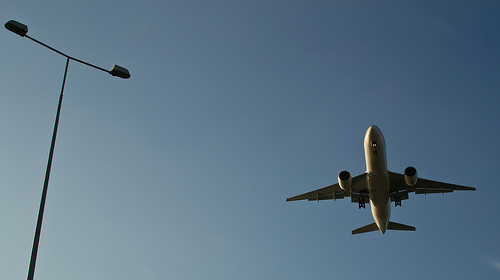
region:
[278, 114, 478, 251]
a plane taking off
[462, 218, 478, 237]
a red balloon flying in the air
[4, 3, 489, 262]
a blue sky with plane flying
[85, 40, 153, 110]
a part of a light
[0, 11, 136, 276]
a light fixture hanging from a pole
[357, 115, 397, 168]
a front of the plane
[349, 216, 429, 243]
the tail of the plane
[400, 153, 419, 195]
a right engine of the plane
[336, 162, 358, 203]
a left engine of the plane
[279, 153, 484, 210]
wings of a airplane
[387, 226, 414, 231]
elevator flight control surface on an airplane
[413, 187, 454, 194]
landing flaps on an airplane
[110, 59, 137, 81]
light fixture on outdoor lighting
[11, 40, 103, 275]
support structure for outdoor lights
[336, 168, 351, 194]
jet engine on passenger jet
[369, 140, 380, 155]
landing gear or on passenger jet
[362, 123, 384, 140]
flightdeck on a passenger jet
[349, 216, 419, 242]
horizontal stabilizers on an airplane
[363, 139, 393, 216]
main fuselage of passenger jet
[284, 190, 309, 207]
wing tip on a commercial airliner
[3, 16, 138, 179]
Lights on a pole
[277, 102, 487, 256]
Airplane in the sky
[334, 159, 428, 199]
Twin engines on a plane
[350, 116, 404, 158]
Silver nose of an airplane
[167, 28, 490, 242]
A cloudless sky where a plane flies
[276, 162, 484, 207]
Wings and engines of an airplane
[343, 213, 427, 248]
The tail of a plane in flight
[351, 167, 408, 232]
Landing gear lowering on a plane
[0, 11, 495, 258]
A plane preparing for landing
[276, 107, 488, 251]
Silver airplane ready for landing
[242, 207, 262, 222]
the sky is clear and blue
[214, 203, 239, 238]
the sky is clear and blue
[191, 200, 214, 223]
the sky is clear and blue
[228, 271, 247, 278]
the sky is clear and blue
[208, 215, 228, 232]
the sky is clear and blue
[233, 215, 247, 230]
the sky is clear and blue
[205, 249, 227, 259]
the sky is clear and blue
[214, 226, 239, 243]
the sky is clear and blue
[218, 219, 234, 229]
the sky is clear and blue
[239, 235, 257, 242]
the sky is clear and blue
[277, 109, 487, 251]
A jetliner up in the sky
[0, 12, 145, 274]
Street lights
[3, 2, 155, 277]
A tall metal pole with two lights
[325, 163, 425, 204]
Two engines on an airplane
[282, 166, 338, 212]
Airplane wing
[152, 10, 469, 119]
Blue sky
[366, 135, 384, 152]
Front landing gear on an airplane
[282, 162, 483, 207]
Two wings on an airplane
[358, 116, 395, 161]
The nose of an airplane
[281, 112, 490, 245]
The underside of an airplane